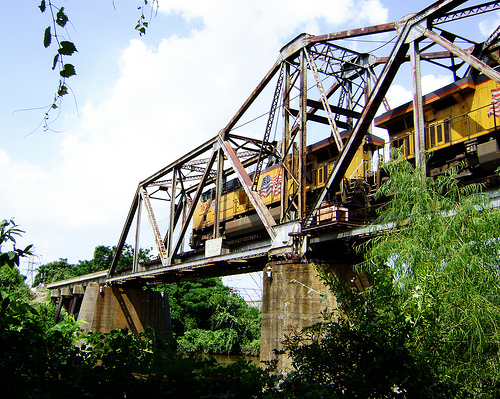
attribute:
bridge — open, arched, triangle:
[29, 3, 498, 378]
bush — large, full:
[351, 144, 497, 397]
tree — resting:
[351, 143, 498, 386]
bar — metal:
[111, 181, 139, 272]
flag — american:
[258, 173, 285, 195]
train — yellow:
[190, 75, 499, 250]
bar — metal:
[211, 133, 230, 255]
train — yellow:
[154, 69, 474, 244]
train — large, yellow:
[184, 102, 495, 238]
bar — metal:
[132, 175, 187, 275]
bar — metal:
[129, 187, 144, 274]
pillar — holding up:
[263, 225, 376, 339]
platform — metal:
[297, 195, 364, 236]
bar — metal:
[102, 195, 133, 275]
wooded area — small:
[55, 250, 149, 374]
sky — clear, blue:
[3, 0, 498, 303]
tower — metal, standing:
[18, 245, 45, 287]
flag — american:
[250, 167, 293, 208]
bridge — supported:
[88, 187, 485, 326]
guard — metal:
[310, 204, 354, 222]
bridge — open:
[40, 270, 100, 290]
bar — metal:
[168, 140, 218, 264]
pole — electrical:
[12, 240, 40, 292]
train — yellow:
[183, 39, 499, 248]